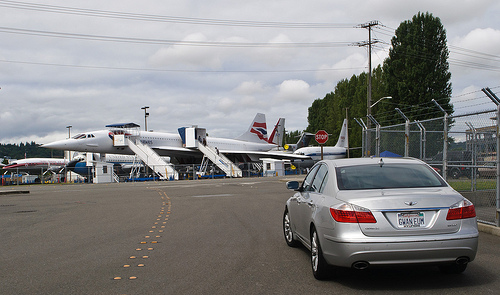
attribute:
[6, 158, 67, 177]
plane — in background, white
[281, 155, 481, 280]
car — silver, moving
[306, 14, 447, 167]
trees — in background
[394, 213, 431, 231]
license plate — white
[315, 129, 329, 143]
stop sign — red, white, at airport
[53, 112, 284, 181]
plane — large, stationary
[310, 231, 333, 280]
tire — black, rubber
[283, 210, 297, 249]
tire — black, rubber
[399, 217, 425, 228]
lettering — black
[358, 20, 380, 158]
pole — wooden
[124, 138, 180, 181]
ramp — white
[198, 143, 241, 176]
ramp — white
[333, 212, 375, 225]
tail light — plastic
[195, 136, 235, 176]
people — walking